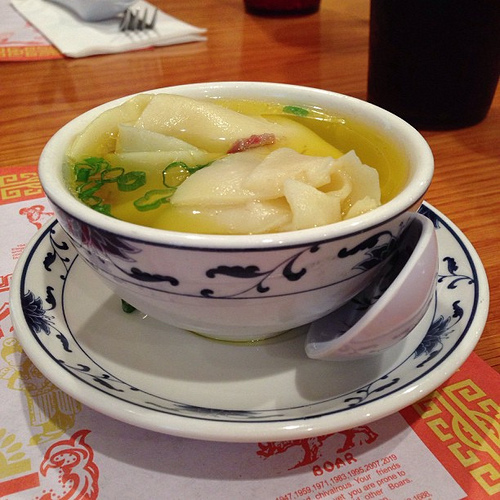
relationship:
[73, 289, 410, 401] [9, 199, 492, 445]
shadow on plate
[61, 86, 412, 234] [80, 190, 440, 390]
food in bowl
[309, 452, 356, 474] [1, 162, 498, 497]
words on place mat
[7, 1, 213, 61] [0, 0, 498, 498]
napkin on a table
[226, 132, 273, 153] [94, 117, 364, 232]
meat in a soup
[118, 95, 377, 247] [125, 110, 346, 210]
wontons in soup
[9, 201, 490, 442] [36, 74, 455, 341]
plate under bowl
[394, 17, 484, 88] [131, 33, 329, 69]
glass on table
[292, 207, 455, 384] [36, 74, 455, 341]
soup spoon next to bowl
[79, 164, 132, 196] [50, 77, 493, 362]
onions in soup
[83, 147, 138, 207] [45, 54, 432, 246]
scallions in soup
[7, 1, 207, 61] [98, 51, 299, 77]
napkin on table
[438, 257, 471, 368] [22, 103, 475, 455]
design on plate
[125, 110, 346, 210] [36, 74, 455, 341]
soup in bowl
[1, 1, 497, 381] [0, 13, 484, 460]
table in scene